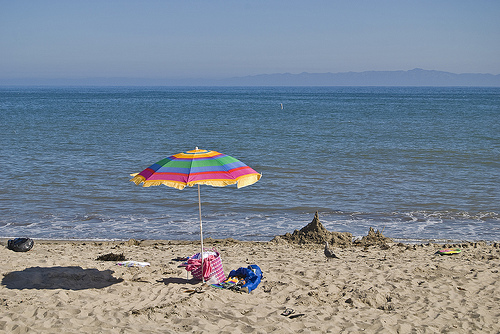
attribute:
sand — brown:
[0, 238, 500, 333]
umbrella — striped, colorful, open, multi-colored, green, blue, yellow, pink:
[128, 146, 263, 290]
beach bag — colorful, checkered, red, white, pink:
[185, 250, 232, 285]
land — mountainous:
[0, 69, 500, 90]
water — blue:
[0, 86, 500, 241]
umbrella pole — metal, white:
[196, 184, 205, 254]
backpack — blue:
[212, 265, 263, 292]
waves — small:
[0, 208, 499, 239]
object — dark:
[6, 238, 34, 252]